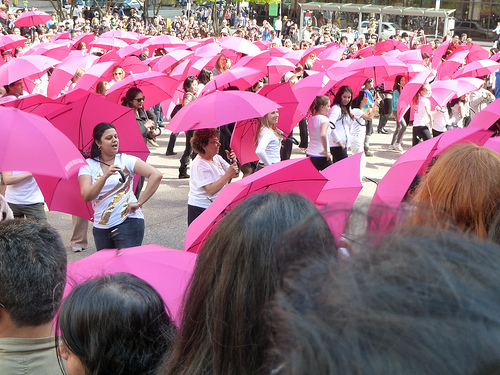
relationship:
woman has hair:
[86, 132, 153, 252] [87, 123, 112, 166]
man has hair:
[1, 208, 70, 369] [8, 228, 62, 312]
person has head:
[190, 203, 298, 369] [225, 226, 304, 283]